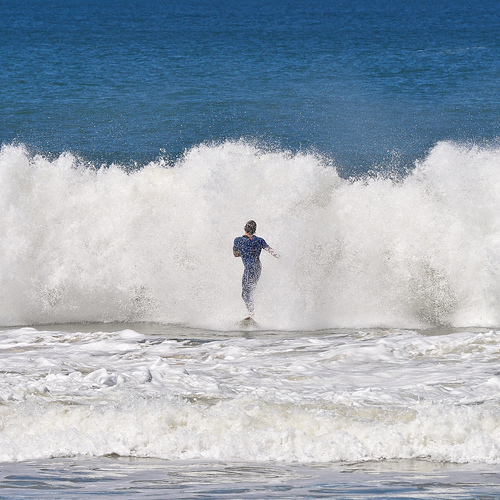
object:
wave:
[2, 389, 498, 466]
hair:
[243, 219, 258, 235]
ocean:
[1, 1, 499, 498]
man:
[232, 219, 282, 318]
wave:
[0, 132, 499, 337]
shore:
[0, 449, 499, 500]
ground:
[430, 151, 480, 204]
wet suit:
[233, 235, 269, 318]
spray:
[352, 130, 410, 175]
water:
[0, 2, 500, 500]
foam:
[72, 390, 354, 477]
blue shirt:
[232, 234, 268, 269]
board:
[235, 316, 262, 332]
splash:
[53, 173, 350, 206]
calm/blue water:
[0, 0, 489, 152]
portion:
[4, 139, 498, 471]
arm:
[259, 237, 281, 260]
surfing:
[231, 216, 281, 331]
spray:
[7, 124, 335, 203]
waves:
[0, 327, 499, 406]